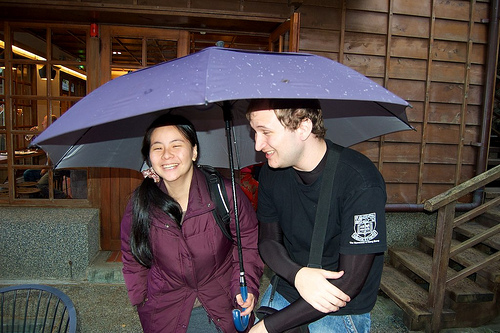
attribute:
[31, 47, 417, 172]
umbrella — purple, white, blue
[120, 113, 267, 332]
woman — smiling, open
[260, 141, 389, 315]
shirt — black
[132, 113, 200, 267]
hair — black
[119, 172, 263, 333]
coat — purple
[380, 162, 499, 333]
stairs — wood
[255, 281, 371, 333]
pants — blue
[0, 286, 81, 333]
seat — metal, black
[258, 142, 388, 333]
sweater — black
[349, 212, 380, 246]
logo — white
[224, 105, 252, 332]
handle — blue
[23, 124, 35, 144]
bottle — clear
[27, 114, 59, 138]
man — bald